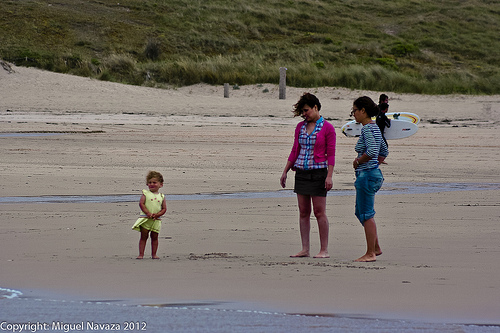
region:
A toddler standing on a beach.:
[128, 163, 174, 267]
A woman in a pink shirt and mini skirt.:
[270, 85, 337, 270]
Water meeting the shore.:
[16, 277, 138, 332]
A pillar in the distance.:
[270, 63, 292, 102]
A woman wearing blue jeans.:
[343, 88, 393, 278]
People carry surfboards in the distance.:
[341, 93, 422, 143]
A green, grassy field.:
[162, 10, 310, 67]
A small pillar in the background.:
[223, 80, 229, 99]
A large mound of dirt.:
[0, 68, 75, 108]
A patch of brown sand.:
[427, 110, 493, 133]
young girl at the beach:
[15, 144, 267, 329]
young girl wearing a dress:
[109, 148, 194, 269]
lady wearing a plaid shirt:
[273, 85, 342, 264]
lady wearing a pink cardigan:
[264, 85, 343, 263]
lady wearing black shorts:
[278, 89, 343, 266]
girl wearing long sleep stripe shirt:
[346, 80, 409, 267]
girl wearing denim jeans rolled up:
[347, 89, 401, 273]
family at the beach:
[71, 47, 436, 319]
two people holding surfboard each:
[338, 77, 438, 151]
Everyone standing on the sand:
[52, 47, 444, 282]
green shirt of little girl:
[131, 186, 165, 208]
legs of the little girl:
[135, 228, 168, 256]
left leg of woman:
[309, 189, 334, 268]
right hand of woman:
[274, 160, 295, 189]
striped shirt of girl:
[352, 126, 388, 162]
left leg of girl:
[355, 203, 385, 255]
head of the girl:
[347, 95, 383, 123]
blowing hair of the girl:
[282, 84, 306, 114]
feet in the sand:
[280, 225, 355, 266]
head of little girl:
[130, 154, 183, 201]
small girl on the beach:
[128, 170, 167, 262]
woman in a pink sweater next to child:
[278, 90, 335, 257]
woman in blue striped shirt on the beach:
[347, 95, 387, 261]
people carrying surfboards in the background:
[341, 93, 420, 140]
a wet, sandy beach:
[1, 56, 497, 326]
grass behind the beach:
[0, 0, 498, 94]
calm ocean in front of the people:
[1, 284, 497, 331]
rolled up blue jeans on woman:
[353, 166, 385, 225]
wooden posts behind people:
[221, 65, 286, 99]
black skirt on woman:
[293, 165, 327, 195]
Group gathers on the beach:
[132, 91, 388, 262]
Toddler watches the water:
[132, 169, 166, 261]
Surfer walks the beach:
[342, 93, 421, 165]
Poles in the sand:
[221, 65, 291, 100]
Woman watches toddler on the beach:
[280, 93, 337, 258]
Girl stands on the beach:
[350, 94, 389, 262]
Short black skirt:
[292, 166, 329, 200]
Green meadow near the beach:
[2, 4, 498, 89]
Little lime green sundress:
[132, 190, 164, 233]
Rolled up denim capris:
[353, 164, 382, 224]